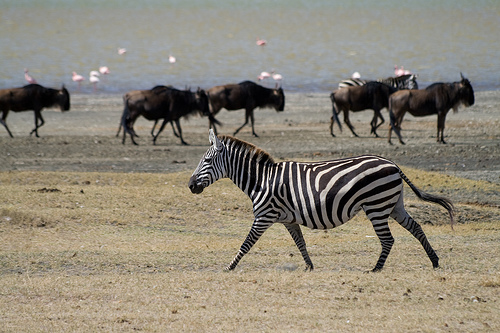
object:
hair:
[215, 135, 274, 167]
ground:
[0, 145, 432, 225]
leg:
[391, 200, 441, 269]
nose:
[187, 180, 195, 189]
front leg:
[223, 215, 274, 270]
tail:
[393, 166, 457, 232]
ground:
[0, 92, 499, 333]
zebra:
[183, 127, 456, 272]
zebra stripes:
[290, 162, 308, 228]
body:
[224, 153, 441, 276]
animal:
[0, 80, 70, 138]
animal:
[385, 73, 477, 147]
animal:
[207, 79, 287, 139]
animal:
[326, 79, 415, 137]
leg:
[281, 220, 316, 272]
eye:
[200, 157, 215, 165]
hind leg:
[362, 200, 396, 273]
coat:
[187, 128, 439, 272]